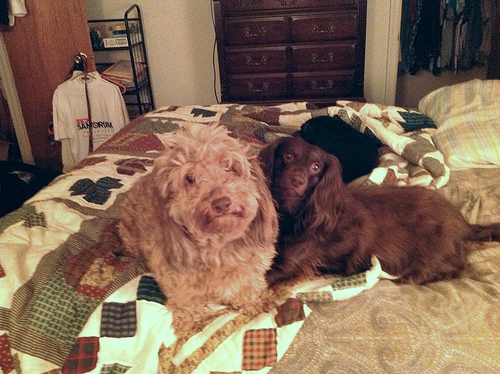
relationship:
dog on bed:
[257, 131, 496, 282] [3, 100, 498, 370]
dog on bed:
[114, 124, 275, 333] [3, 100, 498, 370]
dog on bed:
[95, 124, 276, 333] [3, 100, 498, 370]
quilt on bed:
[300, 86, 446, 180] [81, 97, 463, 345]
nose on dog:
[197, 188, 245, 220] [114, 124, 275, 333]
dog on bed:
[114, 124, 275, 333] [81, 97, 463, 345]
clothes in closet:
[401, 16, 499, 69] [386, 2, 497, 100]